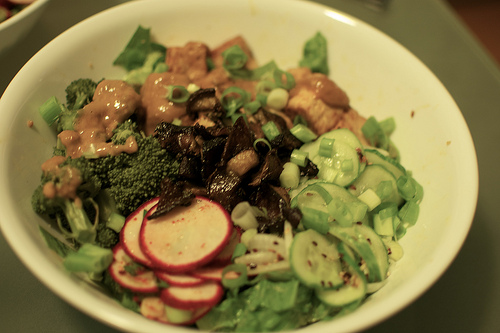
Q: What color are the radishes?
A: White.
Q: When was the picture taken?
A: Last night.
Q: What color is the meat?
A: Brown.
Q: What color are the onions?
A: Green.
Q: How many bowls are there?
A: One.